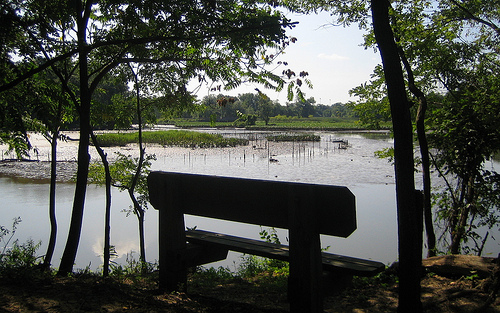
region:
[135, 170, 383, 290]
a bench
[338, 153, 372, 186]
the water at the lake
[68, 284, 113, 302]
the dirt is brown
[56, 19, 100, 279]
the tree is tall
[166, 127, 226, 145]
grass in the lake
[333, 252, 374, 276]
the bench is made of wood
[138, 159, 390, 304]
bench made of wood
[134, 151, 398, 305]
bench in the bank of body of water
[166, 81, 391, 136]
trees on the background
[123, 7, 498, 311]
a trunk next to bench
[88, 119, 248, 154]
green grass in the middle of water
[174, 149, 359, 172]
the water is calm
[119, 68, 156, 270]
the trunk is tiny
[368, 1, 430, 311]
trunk of a tree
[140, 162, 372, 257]
backrest made of one plank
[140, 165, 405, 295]
A bench in the shade.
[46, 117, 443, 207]
A large body of water.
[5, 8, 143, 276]
Tree next to a bench.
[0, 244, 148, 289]
Grass on the ground.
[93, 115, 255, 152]
Marshes in the water.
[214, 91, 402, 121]
A large forest in the background.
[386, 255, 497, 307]
A dirt path on the side of a bench.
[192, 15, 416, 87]
A cloudy sky in the daytime.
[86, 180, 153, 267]
A reflection of clouds in the water.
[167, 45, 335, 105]
Tree branches over a bench.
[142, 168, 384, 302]
Bench next to the water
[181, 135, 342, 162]
Reeds growing in water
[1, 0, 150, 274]
Trees next to water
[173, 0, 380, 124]
Blue sky behind trees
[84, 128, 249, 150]
Grass growing in water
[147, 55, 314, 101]
Leaves on a tree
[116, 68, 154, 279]
Tree sapling next to the water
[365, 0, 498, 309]
Trees next to the water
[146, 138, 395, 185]
Ripples on the water surface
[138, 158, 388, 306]
A bench in a park overlooking a swamp.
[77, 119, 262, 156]
An area of aquatic vegetation.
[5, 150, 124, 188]
A mud flat with dead seaweed.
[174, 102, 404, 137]
A swampy area covered in fronds.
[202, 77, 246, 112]
A bunch of dead leaves on a live tree.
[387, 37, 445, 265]
A small twisted tree trunk.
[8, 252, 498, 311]
Well-worn pathway near a bench.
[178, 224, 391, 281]
The seat of a wooden bench.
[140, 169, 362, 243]
Backrest of a bench.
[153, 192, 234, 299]
Upright support of a bench.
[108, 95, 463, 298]
a wooden bench by a lake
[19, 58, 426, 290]
a wooden bench facing water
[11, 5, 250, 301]
trees along a lake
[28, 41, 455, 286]
water with islands in it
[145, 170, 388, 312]
lakeside bench made of wood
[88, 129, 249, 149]
small grassy island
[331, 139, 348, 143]
dead log floating in the lake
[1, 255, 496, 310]
rocky lake shoreline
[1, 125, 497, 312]
calm shallow lake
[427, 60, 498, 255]
small green lakeside tree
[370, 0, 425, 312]
tall skinny tree trunk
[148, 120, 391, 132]
green grass covered lake shoreline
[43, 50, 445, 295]
this is a nature park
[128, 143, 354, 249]
the bench is black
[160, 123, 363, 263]
the bench is wooden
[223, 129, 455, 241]
the water is brown